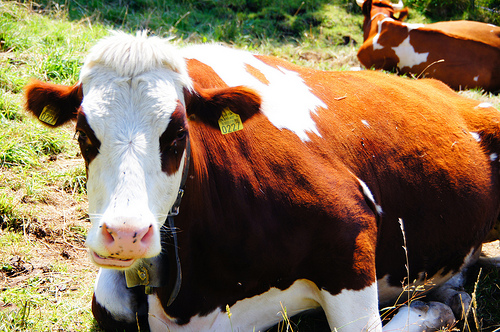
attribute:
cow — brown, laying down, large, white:
[74, 33, 488, 318]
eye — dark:
[75, 127, 95, 149]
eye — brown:
[170, 126, 188, 143]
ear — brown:
[183, 84, 263, 129]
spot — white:
[360, 118, 370, 126]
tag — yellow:
[216, 106, 244, 136]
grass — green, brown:
[0, 0, 499, 331]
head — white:
[24, 28, 264, 271]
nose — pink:
[100, 222, 154, 258]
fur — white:
[84, 28, 189, 78]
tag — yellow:
[39, 105, 59, 127]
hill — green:
[1, 1, 500, 331]